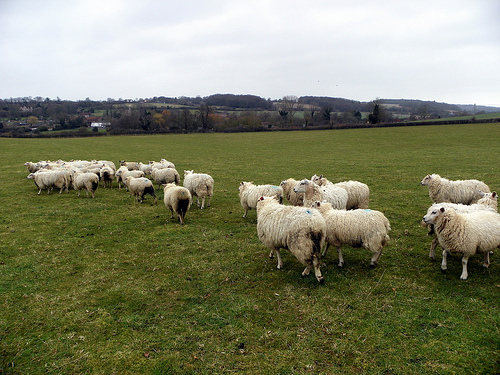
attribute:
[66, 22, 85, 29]
sky — cloudy, hazy, white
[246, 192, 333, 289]
sheep — white, wooly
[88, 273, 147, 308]
grass — green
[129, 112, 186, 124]
trees — green